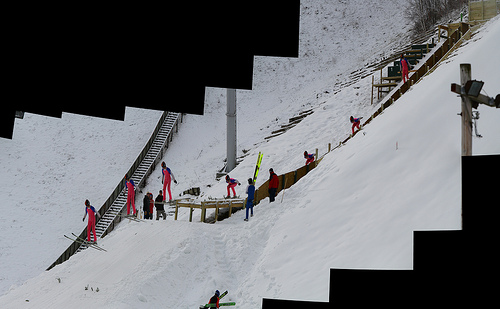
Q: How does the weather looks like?
A: Snowy winter.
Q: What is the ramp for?
A: Ski jumping.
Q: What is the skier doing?
A: Jumping.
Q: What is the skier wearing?
A: Ski suit.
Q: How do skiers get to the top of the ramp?
A: Stairs.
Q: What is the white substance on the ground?
A: Snow.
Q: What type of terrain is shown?
A: Mountain.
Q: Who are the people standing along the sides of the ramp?
A: Spectators.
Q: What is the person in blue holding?
A: Flag.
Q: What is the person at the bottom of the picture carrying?
A: Skis.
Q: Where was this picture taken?
A: A ski slope.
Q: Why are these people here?
A: To ski.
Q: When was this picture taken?
A: Daytime.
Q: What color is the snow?
A: White.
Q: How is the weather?
A: Clear.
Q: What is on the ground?
A: Snow.